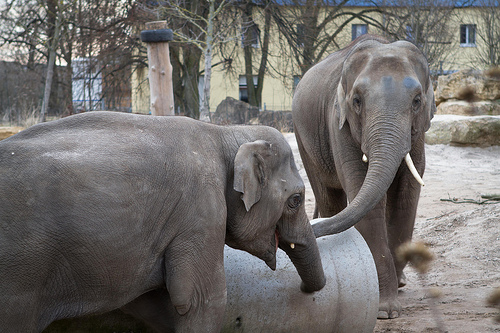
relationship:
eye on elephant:
[286, 189, 307, 211] [0, 112, 324, 331]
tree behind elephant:
[390, 18, 471, 82] [0, 95, 358, 327]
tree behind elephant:
[466, 10, 499, 71] [0, 95, 358, 327]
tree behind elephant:
[230, 19, 272, 94] [0, 95, 358, 327]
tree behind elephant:
[390, 18, 471, 82] [275, 17, 440, 303]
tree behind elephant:
[466, 10, 499, 71] [275, 17, 440, 303]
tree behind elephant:
[230, 19, 272, 94] [275, 17, 440, 303]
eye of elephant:
[351, 97, 364, 112] [287, 36, 436, 319]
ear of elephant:
[231, 140, 274, 212] [286, 22, 454, 255]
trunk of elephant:
[302, 96, 422, 240] [287, 36, 436, 319]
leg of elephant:
[342, 171, 407, 321] [287, 36, 436, 319]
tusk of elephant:
[360, 153, 424, 187] [281, 25, 483, 312]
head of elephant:
[336, 40, 441, 187] [288, 46, 441, 306]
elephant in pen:
[0, 112, 324, 331] [3, 5, 495, 327]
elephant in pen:
[287, 36, 436, 319] [3, 5, 495, 327]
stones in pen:
[429, 62, 499, 149] [3, 5, 495, 327]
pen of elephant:
[3, 5, 495, 327] [0, 110, 329, 332]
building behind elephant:
[177, 18, 499, 110] [0, 110, 329, 332]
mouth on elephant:
[274, 225, 293, 267] [0, 112, 324, 331]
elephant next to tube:
[0, 110, 329, 332] [202, 212, 382, 332]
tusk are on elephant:
[360, 153, 426, 188] [287, 36, 436, 319]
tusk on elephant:
[360, 153, 426, 188] [288, 46, 441, 306]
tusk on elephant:
[289, 241, 295, 248] [13, 98, 332, 328]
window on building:
[458, 20, 480, 46] [133, 0, 500, 117]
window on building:
[350, 20, 367, 46] [133, 0, 500, 117]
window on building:
[238, 70, 260, 103] [133, 0, 500, 117]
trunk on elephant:
[302, 96, 414, 238] [287, 36, 436, 319]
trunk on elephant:
[284, 225, 332, 302] [13, 95, 333, 302]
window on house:
[458, 20, 480, 46] [203, 9, 493, 103]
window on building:
[297, 23, 317, 46] [133, 0, 500, 117]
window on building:
[238, 21, 259, 48] [133, 0, 500, 117]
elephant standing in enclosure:
[0, 112, 324, 331] [1, 12, 482, 331]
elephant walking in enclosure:
[287, 36, 436, 319] [1, 12, 482, 331]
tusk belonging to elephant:
[360, 153, 426, 188] [284, 33, 439, 244]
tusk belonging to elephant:
[289, 241, 295, 248] [0, 112, 324, 331]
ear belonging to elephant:
[218, 143, 289, 213] [0, 112, 324, 331]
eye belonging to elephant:
[412, 96, 421, 108] [287, 36, 436, 319]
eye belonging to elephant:
[351, 97, 364, 112] [287, 36, 436, 319]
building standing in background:
[133, 0, 500, 117] [1, 1, 481, 114]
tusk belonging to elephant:
[360, 153, 426, 188] [287, 36, 436, 319]